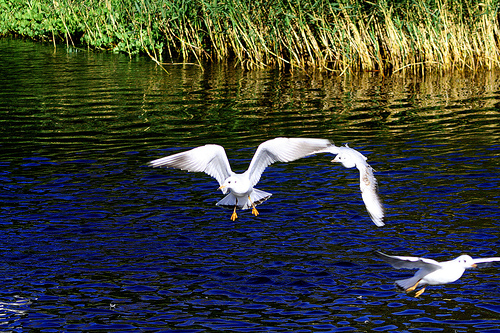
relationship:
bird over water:
[145, 137, 333, 221] [49, 238, 129, 306]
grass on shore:
[2, 3, 492, 70] [2, 35, 498, 65]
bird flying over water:
[368, 249, 500, 297] [1, 28, 495, 324]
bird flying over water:
[300, 143, 385, 228] [1, 28, 495, 324]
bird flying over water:
[145, 137, 333, 221] [1, 28, 495, 324]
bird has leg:
[149, 136, 327, 218] [223, 204, 243, 224]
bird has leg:
[149, 136, 327, 218] [245, 200, 261, 219]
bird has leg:
[368, 241, 499, 301] [399, 282, 419, 294]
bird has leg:
[149, 136, 327, 218] [413, 288, 430, 302]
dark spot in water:
[23, 150, 132, 280] [1, 28, 495, 324]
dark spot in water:
[76, 266, 129, 288] [34, 184, 174, 291]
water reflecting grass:
[328, 63, 450, 133] [0, 0, 499, 79]